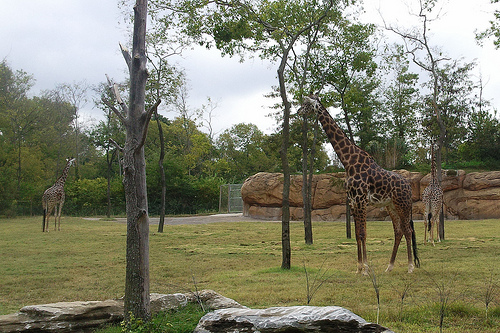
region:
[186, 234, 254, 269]
part of some dry grass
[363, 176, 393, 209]
stomach of a giraffe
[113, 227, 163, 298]
stem of a giraffe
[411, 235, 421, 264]
tail of a giraffe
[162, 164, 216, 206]
green leaves of some trees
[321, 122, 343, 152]
neck of a giraffe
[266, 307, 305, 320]
part of a stone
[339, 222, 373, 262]
front legs of a giraffe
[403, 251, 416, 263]
hind legs of a giraffe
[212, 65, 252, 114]
part of the cloudy sky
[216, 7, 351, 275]
the tree is tall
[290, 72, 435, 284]
the animal is tall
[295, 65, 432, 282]
the animal is a giraffe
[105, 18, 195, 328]
the bark is gray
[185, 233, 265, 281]
the grass is green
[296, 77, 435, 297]
the animal is standing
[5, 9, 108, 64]
the sky is blue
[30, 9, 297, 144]
the sky is cloudy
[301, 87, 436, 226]
the giraffe has spots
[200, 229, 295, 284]
the grass is short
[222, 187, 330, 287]
the grass is green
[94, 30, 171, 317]
the tree is brown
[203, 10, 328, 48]
the leaves are green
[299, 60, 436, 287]
the giraffe is standing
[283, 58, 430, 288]
the giraffe is eating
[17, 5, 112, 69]
the clouds are white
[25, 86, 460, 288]
there are three giraffes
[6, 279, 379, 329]
large rocks surrounding a tree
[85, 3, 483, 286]
many small delicate trees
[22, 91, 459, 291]
three giraffes in a field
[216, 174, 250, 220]
a fence behind the field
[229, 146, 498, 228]
a tall rock wall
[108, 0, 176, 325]
a bare tree trunk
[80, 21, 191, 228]
many branches snapped short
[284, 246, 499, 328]
spindly little shrubs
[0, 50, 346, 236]
a green forest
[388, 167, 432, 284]
a very long black tail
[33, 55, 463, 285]
giraffes standing on grass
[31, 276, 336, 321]
flat rocks around base of trunk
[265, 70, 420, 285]
giraffe's face close to tree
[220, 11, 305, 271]
thin tree trunk dividing into two branches at top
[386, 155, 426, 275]
long tail touching ground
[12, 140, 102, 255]
giraffe heading to back of enclosure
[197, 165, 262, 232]
fencing in back of large wall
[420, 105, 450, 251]
giraffe in front of a tree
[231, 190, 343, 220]
horizontal crevice in rock wall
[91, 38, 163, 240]
stumps of dead branches on a tree